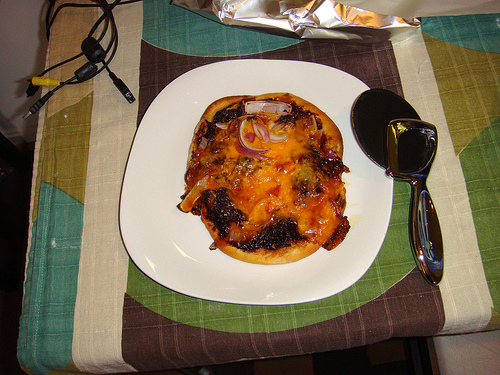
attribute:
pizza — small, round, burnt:
[206, 104, 368, 268]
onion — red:
[235, 114, 271, 161]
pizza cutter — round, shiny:
[349, 83, 452, 288]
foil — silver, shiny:
[233, 5, 418, 43]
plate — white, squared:
[115, 57, 396, 318]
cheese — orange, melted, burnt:
[230, 142, 287, 219]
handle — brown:
[407, 175, 451, 278]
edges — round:
[113, 69, 210, 146]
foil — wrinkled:
[238, 8, 303, 34]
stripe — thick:
[392, 20, 494, 304]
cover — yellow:
[25, 72, 73, 87]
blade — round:
[342, 89, 392, 151]